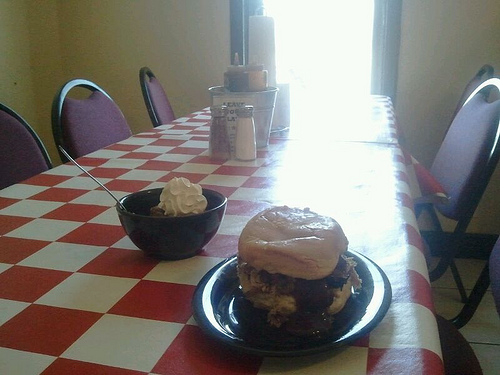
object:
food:
[236, 204, 363, 335]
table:
[7, 262, 172, 374]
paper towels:
[248, 15, 276, 88]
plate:
[191, 248, 392, 357]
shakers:
[209, 104, 231, 159]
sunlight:
[292, 78, 387, 197]